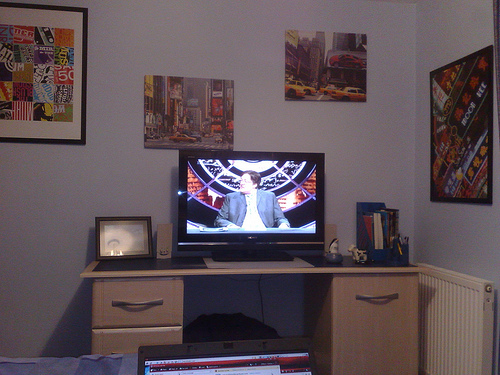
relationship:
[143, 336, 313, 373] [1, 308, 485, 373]
laptop in foreground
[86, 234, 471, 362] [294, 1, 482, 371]
desk in corner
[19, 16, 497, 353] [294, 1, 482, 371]
room has corner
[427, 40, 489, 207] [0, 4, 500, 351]
artwork on wall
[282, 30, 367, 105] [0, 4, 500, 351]
artwork on wall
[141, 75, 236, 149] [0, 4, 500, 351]
artwork on wall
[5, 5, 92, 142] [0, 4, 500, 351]
artwork on wall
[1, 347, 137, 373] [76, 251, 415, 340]
pillow in front of desk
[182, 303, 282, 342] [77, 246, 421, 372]
object under desk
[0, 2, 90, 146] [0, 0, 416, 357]
artwork on wall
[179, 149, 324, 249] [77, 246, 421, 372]
television playing on desk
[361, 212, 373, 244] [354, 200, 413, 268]
book in rack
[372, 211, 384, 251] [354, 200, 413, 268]
book in rack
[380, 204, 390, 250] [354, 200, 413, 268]
book in rack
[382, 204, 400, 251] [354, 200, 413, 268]
book in rack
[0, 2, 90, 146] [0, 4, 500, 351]
artwork on wall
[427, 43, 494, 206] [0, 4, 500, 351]
artwork on wall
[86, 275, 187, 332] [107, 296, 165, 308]
drawer has handle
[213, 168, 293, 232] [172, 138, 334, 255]
person on television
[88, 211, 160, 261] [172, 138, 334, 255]
photo next to television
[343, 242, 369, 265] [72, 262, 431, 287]
cow on desk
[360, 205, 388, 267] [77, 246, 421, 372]
holder on desk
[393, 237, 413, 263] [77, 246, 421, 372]
holder on desk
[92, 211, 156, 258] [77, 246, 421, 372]
certificate on desk